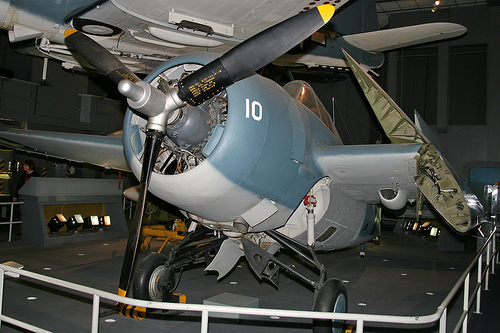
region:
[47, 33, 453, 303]
small plane on exhibit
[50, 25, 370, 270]
propeller in front of plane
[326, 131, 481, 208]
broken wing with wires exposed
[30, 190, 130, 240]
panel of lights on floor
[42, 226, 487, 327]
white railing surrounding plane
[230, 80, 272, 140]
number printed on side of plane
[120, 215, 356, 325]
metal frame supporting plane wheels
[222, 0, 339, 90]
yellow tip on black blade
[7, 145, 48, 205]
person in aisle of museum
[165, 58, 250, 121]
tiny yellow print on base of propeller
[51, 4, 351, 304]
Big propeller on plane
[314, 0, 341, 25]
Tip of propeller is yellow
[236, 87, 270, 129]
Number 10 in the plane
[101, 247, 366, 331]
Front wheels of plane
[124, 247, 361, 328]
Wheels are black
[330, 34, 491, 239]
Right wing of plane is broken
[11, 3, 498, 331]
Plane is fenced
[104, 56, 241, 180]
Engine of plane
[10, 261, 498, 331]
Rail surround a plane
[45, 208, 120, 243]
Four lights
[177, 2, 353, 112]
black propeller with yellow tip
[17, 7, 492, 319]
old airplane on display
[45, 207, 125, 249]
lights illuminating airplane display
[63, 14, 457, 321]
blue and white airplane on display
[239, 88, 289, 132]
The number 10 in white letters on plane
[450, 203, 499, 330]
White steel gate surrounding display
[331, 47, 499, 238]
wing of airplane opened up for display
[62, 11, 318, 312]
Three black propellers with yellow tips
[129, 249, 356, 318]
Two black wheels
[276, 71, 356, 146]
Plastic covering pilots seat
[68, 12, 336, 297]
this is an propeller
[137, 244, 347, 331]
these are two wheels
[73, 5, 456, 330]
this is an aircraft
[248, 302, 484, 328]
the area is fenced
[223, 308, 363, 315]
the fence is metallic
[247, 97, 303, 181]
the aircraft is blue in color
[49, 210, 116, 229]
there are four lights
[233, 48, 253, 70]
the propeller arm is black in color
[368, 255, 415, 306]
the floor is shiny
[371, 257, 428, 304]
the floor is slippery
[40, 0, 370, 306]
Propeller of plane is black and yellow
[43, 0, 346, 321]
Propeller of plane is big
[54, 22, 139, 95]
Tip of propeller yellow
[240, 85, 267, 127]
Number 10 on plane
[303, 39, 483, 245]
Wing of plane is broken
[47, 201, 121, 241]
Four light on a small wall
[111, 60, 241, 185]
Engine of propeller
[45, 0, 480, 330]
Broken plane is indoor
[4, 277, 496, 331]
Rail around the plane